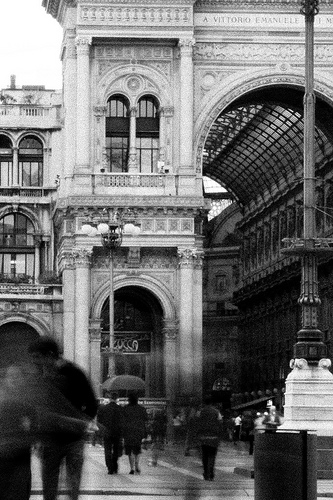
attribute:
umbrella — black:
[187, 388, 232, 418]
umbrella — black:
[99, 370, 150, 397]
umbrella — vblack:
[79, 213, 144, 246]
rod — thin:
[119, 391, 125, 409]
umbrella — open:
[99, 370, 151, 394]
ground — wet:
[31, 439, 242, 491]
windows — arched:
[95, 91, 165, 170]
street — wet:
[24, 424, 315, 489]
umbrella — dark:
[101, 369, 153, 395]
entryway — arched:
[96, 280, 170, 401]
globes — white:
[79, 219, 148, 240]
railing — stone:
[97, 174, 163, 189]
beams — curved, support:
[195, 59, 320, 204]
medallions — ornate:
[240, 191, 319, 264]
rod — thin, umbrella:
[118, 391, 124, 404]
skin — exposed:
[122, 455, 143, 468]